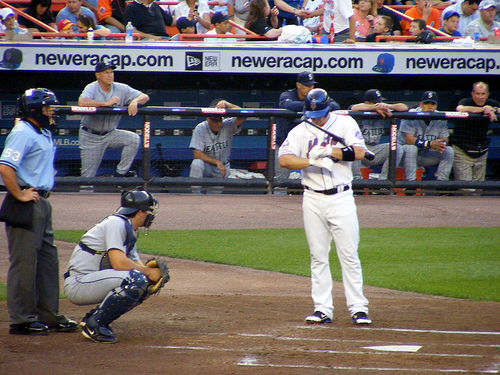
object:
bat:
[303, 119, 375, 162]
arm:
[329, 123, 366, 162]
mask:
[139, 197, 162, 229]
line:
[294, 325, 499, 335]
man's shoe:
[8, 318, 50, 338]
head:
[116, 186, 158, 231]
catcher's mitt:
[145, 254, 170, 296]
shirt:
[0, 119, 58, 196]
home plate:
[360, 341, 422, 357]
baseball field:
[0, 193, 497, 374]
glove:
[308, 155, 336, 173]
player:
[274, 87, 374, 328]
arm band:
[340, 145, 358, 163]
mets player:
[274, 88, 373, 325]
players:
[186, 100, 252, 197]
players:
[349, 89, 409, 197]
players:
[271, 70, 342, 196]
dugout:
[0, 69, 499, 198]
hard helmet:
[303, 89, 333, 121]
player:
[74, 61, 150, 193]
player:
[452, 80, 497, 197]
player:
[395, 90, 455, 198]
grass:
[48, 227, 499, 302]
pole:
[376, 32, 489, 44]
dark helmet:
[14, 87, 59, 125]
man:
[0, 87, 82, 337]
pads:
[90, 268, 150, 323]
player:
[62, 187, 172, 344]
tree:
[444, 235, 467, 271]